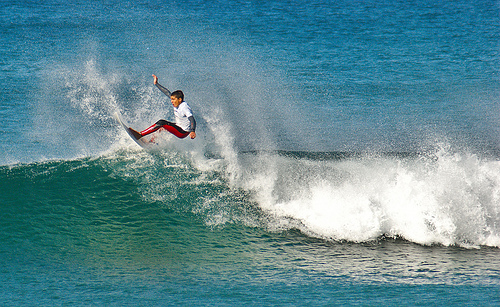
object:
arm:
[151, 84, 170, 99]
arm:
[182, 109, 197, 135]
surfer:
[134, 78, 213, 154]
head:
[168, 89, 185, 108]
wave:
[0, 0, 499, 306]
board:
[114, 110, 164, 158]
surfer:
[126, 72, 198, 143]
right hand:
[150, 74, 158, 87]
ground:
[399, 168, 444, 212]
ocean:
[0, 0, 499, 306]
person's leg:
[138, 119, 189, 139]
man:
[125, 74, 197, 145]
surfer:
[108, 75, 212, 164]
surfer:
[148, 65, 205, 147]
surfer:
[118, 69, 202, 163]